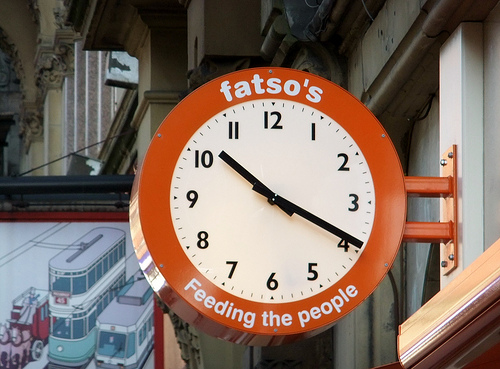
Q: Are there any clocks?
A: Yes, there is a clock.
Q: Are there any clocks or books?
A: Yes, there is a clock.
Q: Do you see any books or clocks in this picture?
A: Yes, there is a clock.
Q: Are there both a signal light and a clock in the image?
A: No, there is a clock but no traffic lights.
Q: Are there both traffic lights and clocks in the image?
A: No, there is a clock but no traffic lights.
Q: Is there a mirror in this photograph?
A: No, there are no mirrors.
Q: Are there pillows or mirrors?
A: No, there are no mirrors or pillows.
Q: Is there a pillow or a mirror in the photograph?
A: No, there are no mirrors or pillows.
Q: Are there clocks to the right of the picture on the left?
A: Yes, there is a clock to the right of the picture.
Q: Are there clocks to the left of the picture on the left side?
A: No, the clock is to the right of the picture.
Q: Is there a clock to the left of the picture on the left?
A: No, the clock is to the right of the picture.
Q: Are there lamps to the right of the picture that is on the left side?
A: No, there is a clock to the right of the picture.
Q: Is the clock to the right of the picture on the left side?
A: Yes, the clock is to the right of the picture.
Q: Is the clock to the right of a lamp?
A: No, the clock is to the right of the picture.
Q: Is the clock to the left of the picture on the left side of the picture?
A: No, the clock is to the right of the picture.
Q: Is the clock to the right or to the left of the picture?
A: The clock is to the right of the picture.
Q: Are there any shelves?
A: No, there are no shelves.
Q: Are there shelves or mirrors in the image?
A: No, there are no shelves or mirrors.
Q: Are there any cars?
A: No, there are no cars.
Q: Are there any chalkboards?
A: No, there are no chalkboards.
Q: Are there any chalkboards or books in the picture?
A: No, there are no chalkboards or books.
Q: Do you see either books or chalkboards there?
A: No, there are no chalkboards or books.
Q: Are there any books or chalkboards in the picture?
A: No, there are no chalkboards or books.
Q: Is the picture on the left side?
A: Yes, the picture is on the left of the image.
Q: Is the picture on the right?
A: No, the picture is on the left of the image.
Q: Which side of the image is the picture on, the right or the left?
A: The picture is on the left of the image.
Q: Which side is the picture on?
A: The picture is on the left of the image.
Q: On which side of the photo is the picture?
A: The picture is on the left of the image.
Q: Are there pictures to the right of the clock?
A: No, the picture is to the left of the clock.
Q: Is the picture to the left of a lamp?
A: No, the picture is to the left of the clock.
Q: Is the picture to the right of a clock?
A: No, the picture is to the left of a clock.